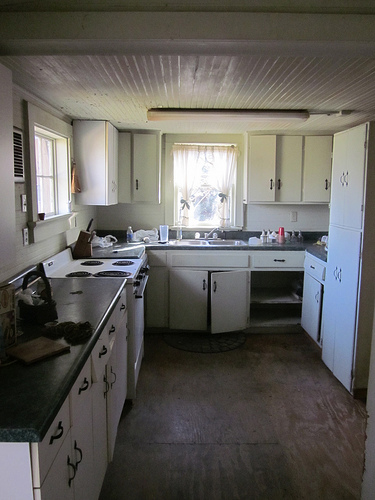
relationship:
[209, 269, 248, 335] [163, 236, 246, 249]
cabinet under sink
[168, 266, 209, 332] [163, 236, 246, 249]
cabinet under sink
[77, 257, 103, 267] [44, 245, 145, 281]
burner on stovetop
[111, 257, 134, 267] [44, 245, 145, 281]
burner on stovetop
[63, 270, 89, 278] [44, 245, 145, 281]
burner on stovetop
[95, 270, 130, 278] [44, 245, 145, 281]
burner on stovetop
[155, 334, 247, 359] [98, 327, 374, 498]
rug on floor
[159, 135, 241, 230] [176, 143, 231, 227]
frame on window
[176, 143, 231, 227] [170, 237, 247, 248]
window above sink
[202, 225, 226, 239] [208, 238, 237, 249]
faucet over sink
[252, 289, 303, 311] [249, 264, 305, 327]
shelf in cabinet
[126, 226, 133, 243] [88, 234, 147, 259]
bottle on counter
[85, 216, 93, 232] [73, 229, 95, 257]
knife in knife block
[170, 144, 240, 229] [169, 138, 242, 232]
curtain covering window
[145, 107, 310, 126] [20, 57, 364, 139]
light mounted on ceiling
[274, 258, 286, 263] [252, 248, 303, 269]
drawer handle on drawer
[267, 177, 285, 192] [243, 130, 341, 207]
handles are on cabinets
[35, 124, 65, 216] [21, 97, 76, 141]
window has frame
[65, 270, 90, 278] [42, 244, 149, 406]
burner on top of stove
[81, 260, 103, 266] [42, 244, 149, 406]
burner on top of stove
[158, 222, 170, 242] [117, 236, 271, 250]
glass on counter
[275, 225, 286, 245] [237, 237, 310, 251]
container on counter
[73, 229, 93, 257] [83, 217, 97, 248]
block has knives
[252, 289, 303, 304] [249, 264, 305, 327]
shelf in cabinet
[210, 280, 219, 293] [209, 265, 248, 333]
handle on door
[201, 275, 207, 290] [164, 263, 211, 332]
handle on door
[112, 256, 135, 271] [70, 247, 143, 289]
jet on stove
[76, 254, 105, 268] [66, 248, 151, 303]
jet on stove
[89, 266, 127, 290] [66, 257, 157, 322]
jet on stove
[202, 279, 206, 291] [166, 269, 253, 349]
handle of cabinet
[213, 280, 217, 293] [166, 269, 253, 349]
handle of cabinet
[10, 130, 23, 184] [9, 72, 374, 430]
vent in kitchen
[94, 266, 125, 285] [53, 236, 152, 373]
burner on a stove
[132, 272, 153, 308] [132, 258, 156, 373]
handle of oven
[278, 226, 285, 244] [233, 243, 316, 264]
container on counter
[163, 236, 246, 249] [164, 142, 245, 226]
sink in front of a window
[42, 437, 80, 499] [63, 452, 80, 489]
cabient has handle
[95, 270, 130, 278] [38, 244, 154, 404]
burner on stove top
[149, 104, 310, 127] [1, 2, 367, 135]
light on ceiling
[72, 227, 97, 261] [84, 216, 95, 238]
block for knives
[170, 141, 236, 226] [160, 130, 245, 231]
curtain on window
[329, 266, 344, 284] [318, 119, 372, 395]
knob on cabinet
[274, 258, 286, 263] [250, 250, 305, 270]
drawer handle on drawer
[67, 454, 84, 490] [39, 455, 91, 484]
handle on cabinet